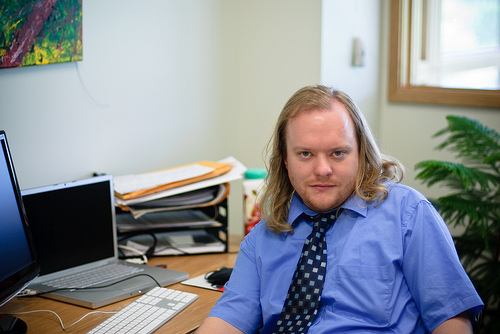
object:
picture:
[0, 0, 83, 69]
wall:
[0, 69, 236, 189]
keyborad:
[84, 287, 200, 334]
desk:
[0, 239, 241, 334]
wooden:
[33, 307, 100, 327]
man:
[256, 84, 404, 234]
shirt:
[205, 181, 482, 334]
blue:
[275, 211, 348, 330]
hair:
[257, 84, 406, 235]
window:
[377, 0, 500, 106]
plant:
[413, 116, 496, 333]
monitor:
[18, 175, 118, 276]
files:
[114, 156, 247, 209]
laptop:
[20, 167, 189, 309]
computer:
[21, 181, 187, 308]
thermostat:
[352, 38, 365, 67]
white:
[86, 287, 198, 334]